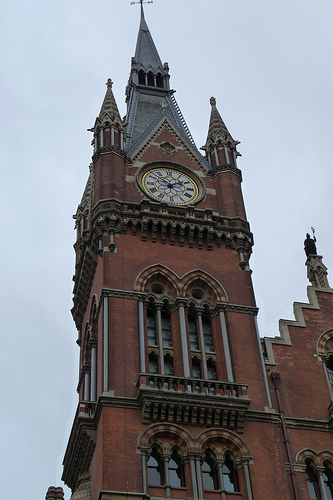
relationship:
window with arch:
[136, 419, 198, 497] [136, 423, 194, 456]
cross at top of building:
[124, 0, 161, 21] [41, 6, 325, 437]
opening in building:
[135, 66, 147, 87] [45, 0, 332, 499]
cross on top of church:
[129, 0, 154, 18] [44, 0, 331, 499]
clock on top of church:
[142, 168, 199, 205] [44, 0, 331, 499]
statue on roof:
[304, 224, 317, 257] [296, 228, 332, 287]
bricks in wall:
[254, 425, 280, 495] [96, 403, 298, 496]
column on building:
[102, 297, 108, 392] [45, 0, 332, 499]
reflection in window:
[204, 459, 235, 491] [195, 428, 253, 498]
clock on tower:
[142, 168, 199, 205] [70, 0, 272, 414]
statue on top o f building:
[304, 224, 317, 257] [2, 0, 332, 498]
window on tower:
[135, 416, 204, 498] [73, 10, 290, 497]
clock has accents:
[142, 168, 199, 205] [136, 160, 207, 206]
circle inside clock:
[154, 174, 188, 197] [142, 168, 199, 205]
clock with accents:
[142, 168, 199, 205] [144, 165, 199, 203]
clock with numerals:
[142, 168, 199, 205] [153, 165, 191, 189]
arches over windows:
[129, 261, 272, 300] [127, 309, 293, 406]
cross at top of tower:
[129, 0, 154, 18] [73, 10, 290, 497]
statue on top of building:
[303, 224, 319, 266] [2, 0, 332, 498]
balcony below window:
[135, 370, 252, 433] [122, 257, 240, 380]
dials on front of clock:
[155, 176, 184, 195] [137, 164, 201, 204]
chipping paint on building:
[275, 311, 331, 343] [259, 214, 330, 497]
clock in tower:
[136, 155, 205, 206] [68, 7, 268, 484]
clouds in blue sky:
[2, 302, 64, 386] [2, 5, 329, 112]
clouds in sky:
[195, 30, 307, 91] [2, 1, 327, 307]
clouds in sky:
[251, 68, 328, 178] [1, 1, 332, 499]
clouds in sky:
[204, 11, 282, 67] [0, 0, 331, 178]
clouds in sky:
[7, 27, 99, 123] [10, 17, 100, 79]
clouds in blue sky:
[16, 60, 67, 123] [0, 1, 332, 499]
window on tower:
[130, 280, 265, 391] [73, 10, 290, 497]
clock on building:
[142, 168, 199, 205] [2, 0, 332, 498]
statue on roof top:
[304, 224, 317, 257] [54, 2, 332, 414]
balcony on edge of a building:
[135, 370, 252, 433] [2, 0, 332, 498]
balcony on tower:
[126, 377, 254, 424] [69, 13, 330, 498]